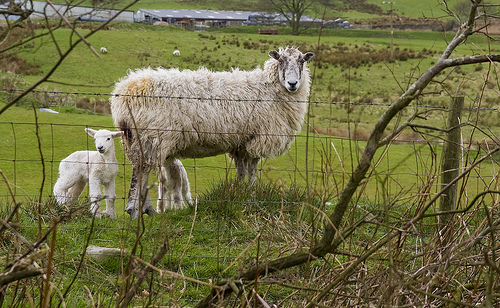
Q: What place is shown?
A: It is a field.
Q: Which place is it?
A: It is a field.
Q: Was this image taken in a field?
A: Yes, it was taken in a field.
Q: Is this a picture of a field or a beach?
A: It is showing a field.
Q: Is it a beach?
A: No, it is a field.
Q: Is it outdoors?
A: Yes, it is outdoors.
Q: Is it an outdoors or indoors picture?
A: It is outdoors.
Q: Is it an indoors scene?
A: No, it is outdoors.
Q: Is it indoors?
A: No, it is outdoors.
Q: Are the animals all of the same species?
A: Yes, all the animals are sheep.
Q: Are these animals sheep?
A: Yes, all the animals are sheep.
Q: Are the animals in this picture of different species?
A: No, all the animals are sheep.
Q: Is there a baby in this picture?
A: Yes, there is a baby.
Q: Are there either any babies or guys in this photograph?
A: Yes, there is a baby.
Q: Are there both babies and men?
A: No, there is a baby but no men.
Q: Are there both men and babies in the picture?
A: No, there is a baby but no men.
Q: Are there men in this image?
A: No, there are no men.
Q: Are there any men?
A: No, there are no men.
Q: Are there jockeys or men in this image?
A: No, there are no men or jockeys.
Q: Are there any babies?
A: Yes, there is a baby.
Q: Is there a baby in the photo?
A: Yes, there is a baby.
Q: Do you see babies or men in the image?
A: Yes, there is a baby.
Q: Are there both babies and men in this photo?
A: No, there is a baby but no men.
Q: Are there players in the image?
A: No, there are no players.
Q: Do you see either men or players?
A: No, there are no players or men.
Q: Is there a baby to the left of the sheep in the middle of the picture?
A: Yes, there is a baby to the left of the sheep.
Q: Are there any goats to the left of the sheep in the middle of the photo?
A: No, there is a baby to the left of the sheep.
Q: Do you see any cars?
A: No, there are no cars.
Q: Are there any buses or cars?
A: No, there are no cars or buses.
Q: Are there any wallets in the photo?
A: No, there are no wallets.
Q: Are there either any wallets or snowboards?
A: No, there are no wallets or snowboards.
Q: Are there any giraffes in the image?
A: No, there are no giraffes.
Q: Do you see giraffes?
A: No, there are no giraffes.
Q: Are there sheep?
A: Yes, there is a sheep.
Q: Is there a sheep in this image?
A: Yes, there is a sheep.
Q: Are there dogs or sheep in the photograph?
A: Yes, there is a sheep.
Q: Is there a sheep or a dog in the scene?
A: Yes, there is a sheep.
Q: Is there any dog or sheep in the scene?
A: Yes, there is a sheep.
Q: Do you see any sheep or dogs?
A: Yes, there is a sheep.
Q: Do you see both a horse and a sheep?
A: No, there is a sheep but no horses.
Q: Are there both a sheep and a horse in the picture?
A: No, there is a sheep but no horses.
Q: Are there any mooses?
A: No, there are no mooses.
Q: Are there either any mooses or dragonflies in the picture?
A: No, there are no mooses or dragonflies.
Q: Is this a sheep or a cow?
A: This is a sheep.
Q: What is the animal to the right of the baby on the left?
A: The animal is a sheep.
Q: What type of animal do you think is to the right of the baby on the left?
A: The animal is a sheep.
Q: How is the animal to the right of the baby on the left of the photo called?
A: The animal is a sheep.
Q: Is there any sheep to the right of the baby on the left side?
A: Yes, there is a sheep to the right of the baby.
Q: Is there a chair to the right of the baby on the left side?
A: No, there is a sheep to the right of the baby.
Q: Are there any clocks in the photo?
A: No, there are no clocks.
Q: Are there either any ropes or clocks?
A: No, there are no clocks or ropes.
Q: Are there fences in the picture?
A: Yes, there is a fence.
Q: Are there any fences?
A: Yes, there is a fence.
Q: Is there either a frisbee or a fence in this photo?
A: Yes, there is a fence.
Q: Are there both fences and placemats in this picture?
A: No, there is a fence but no placemats.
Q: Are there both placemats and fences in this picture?
A: No, there is a fence but no placemats.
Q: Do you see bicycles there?
A: No, there are no bicycles.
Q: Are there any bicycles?
A: No, there are no bicycles.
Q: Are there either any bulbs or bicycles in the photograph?
A: No, there are no bicycles or bulbs.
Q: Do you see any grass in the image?
A: Yes, there is grass.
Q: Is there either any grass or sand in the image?
A: Yes, there is grass.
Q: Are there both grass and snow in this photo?
A: No, there is grass but no snow.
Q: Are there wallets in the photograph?
A: No, there are no wallets.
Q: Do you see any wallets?
A: No, there are no wallets.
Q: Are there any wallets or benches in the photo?
A: No, there are no wallets or benches.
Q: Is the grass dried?
A: Yes, the grass is dried.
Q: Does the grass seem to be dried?
A: Yes, the grass is dried.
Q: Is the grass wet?
A: No, the grass is dried.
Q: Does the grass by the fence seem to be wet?
A: No, the grass is dried.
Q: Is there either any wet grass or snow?
A: No, there is grass but it is dried.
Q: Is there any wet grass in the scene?
A: No, there is grass but it is dried.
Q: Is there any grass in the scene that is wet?
A: No, there is grass but it is dried.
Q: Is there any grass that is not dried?
A: No, there is grass but it is dried.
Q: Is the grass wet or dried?
A: The grass is dried.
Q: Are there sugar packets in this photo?
A: No, there are no sugar packets.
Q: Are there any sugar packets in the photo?
A: No, there are no sugar packets.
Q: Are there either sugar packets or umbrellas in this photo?
A: No, there are no sugar packets or umbrellas.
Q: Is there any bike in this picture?
A: No, there are no bikes.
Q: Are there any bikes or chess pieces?
A: No, there are no bikes or chess pieces.